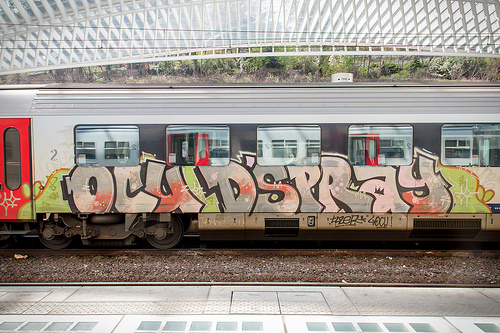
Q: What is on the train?
A: Painting.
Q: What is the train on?
A: Tracks.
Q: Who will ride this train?
A: People.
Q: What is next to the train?
A: Gravel.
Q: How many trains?
A: 1.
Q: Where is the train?
A: Station.